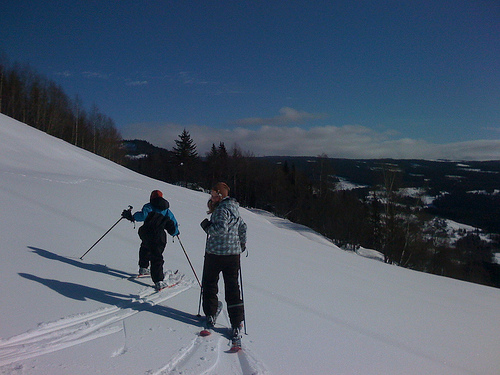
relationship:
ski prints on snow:
[18, 306, 105, 363] [6, 247, 338, 373]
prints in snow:
[151, 339, 260, 374] [284, 275, 497, 364]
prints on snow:
[151, 339, 260, 374] [314, 275, 437, 340]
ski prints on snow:
[18, 277, 229, 374] [3, 110, 484, 372]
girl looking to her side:
[200, 180, 246, 331] [177, 200, 202, 313]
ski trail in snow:
[7, 267, 179, 369] [7, 265, 499, 369]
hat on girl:
[204, 180, 234, 211] [197, 171, 247, 351]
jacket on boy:
[133, 202, 179, 246] [82, 191, 205, 303]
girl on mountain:
[200, 180, 248, 339] [2, 111, 346, 372]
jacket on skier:
[135, 201, 179, 247] [118, 186, 181, 289]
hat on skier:
[150, 189, 163, 202] [125, 187, 180, 291]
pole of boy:
[237, 251, 250, 336] [121, 187, 182, 290]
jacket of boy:
[201, 196, 248, 257] [121, 187, 182, 290]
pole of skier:
[237, 251, 250, 336] [197, 177, 251, 337]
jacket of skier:
[201, 196, 248, 260] [197, 177, 251, 337]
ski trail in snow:
[7, 267, 226, 374] [3, 110, 484, 372]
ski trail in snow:
[77, 209, 204, 309] [0, 103, 484, 373]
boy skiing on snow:
[121, 187, 182, 290] [3, 110, 484, 372]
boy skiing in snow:
[121, 187, 182, 290] [283, 268, 427, 356]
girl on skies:
[200, 180, 248, 339] [126, 268, 246, 355]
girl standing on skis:
[200, 180, 248, 339] [133, 265, 179, 299]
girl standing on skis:
[200, 180, 248, 339] [128, 270, 254, 362]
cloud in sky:
[236, 103, 338, 128] [2, 1, 499, 166]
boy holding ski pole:
[121, 187, 182, 290] [176, 233, 205, 288]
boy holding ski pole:
[121, 187, 182, 290] [76, 215, 124, 259]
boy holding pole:
[121, 187, 182, 290] [237, 251, 250, 336]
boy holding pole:
[121, 187, 182, 290] [194, 226, 211, 321]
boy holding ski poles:
[121, 187, 182, 290] [84, 206, 196, 296]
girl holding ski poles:
[200, 180, 248, 339] [84, 206, 196, 296]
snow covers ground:
[3, 110, 484, 372] [0, 0, 493, 257]